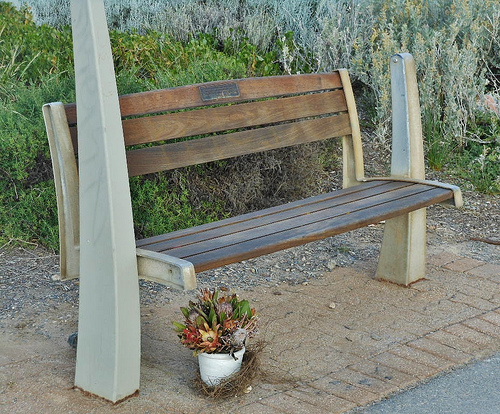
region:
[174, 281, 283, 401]
Potted plant on the ground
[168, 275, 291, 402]
The plant is in a pot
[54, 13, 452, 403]
Empty bench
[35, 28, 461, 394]
The bench is made of wood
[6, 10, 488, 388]
Photo taken during the day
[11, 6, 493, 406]
Nobody in the photo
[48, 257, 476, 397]
Brick pavers in the ground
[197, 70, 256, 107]
Memorial plaque on the bench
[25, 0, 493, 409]
Photo taken outside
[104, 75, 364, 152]
Three wood slats on the upper part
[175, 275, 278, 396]
a white flower pot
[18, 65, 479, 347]
a brown wooden bench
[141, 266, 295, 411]
a flower pot by bench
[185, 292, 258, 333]
green leaves in flower pot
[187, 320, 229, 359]
red and yellow flower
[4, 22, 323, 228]
shrubs behind the bench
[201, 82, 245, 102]
a black plaque on bench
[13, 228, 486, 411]
brick under the bench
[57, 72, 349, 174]
three wood planks on the back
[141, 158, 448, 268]
four wood planks on the bottom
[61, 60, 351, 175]
the boards are made of wood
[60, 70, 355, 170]
the boards are brown in color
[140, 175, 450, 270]
the boards are brown in color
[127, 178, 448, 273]
the boards are made of wood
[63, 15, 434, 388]
the legs are made of metal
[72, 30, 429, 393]
the metal is grey in color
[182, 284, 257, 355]
a plant is on the ground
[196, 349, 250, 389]
a pot is on the ground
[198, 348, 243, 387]
the pot is white in color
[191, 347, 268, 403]
twigs are underneath the pot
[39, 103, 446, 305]
the bench is made of wood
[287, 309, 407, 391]
brick is on the ground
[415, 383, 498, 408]
the gorund is made of cement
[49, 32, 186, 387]
a green pole is next to the bench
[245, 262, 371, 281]
rocks are on the ground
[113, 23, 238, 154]
bushes are behind the bench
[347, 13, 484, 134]
dead bushes are behind the bench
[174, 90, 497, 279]
the bench is brown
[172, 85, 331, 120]
a placard is on the bench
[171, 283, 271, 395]
Plant on the ground.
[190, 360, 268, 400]
Nest under the plant.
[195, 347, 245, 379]
The pot is white.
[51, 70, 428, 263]
The bench is wooden.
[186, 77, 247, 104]
Plaque on the bench.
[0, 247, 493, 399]
The sidewalk is brick.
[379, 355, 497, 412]
The road is grey.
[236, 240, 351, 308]
Rocks on the ground.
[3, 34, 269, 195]
Bush behind the bench.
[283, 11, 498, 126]
The grass is tall.